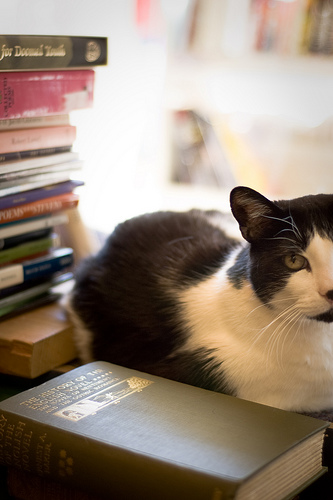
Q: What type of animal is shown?
A: Cat.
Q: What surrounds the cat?
A: Books.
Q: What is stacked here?
A: Books.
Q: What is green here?
A: The book.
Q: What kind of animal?
A: Cat.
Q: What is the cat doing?
A: Sitting.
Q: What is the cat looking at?
A: The camera.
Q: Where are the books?
A: On the table.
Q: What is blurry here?
A: The books.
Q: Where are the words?
A: On the book.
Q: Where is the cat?
A: By the books.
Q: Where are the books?
A: By the cat.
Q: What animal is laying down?
A: A cat.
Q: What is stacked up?
A: Books.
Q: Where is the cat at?
A: Next to books.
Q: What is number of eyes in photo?
A: One.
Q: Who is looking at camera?
A: The cat.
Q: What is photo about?
A: Cat and books.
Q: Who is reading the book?
A: Not the cat.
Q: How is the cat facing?
A: Forward.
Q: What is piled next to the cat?
A: Books.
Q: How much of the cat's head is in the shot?
A: Half.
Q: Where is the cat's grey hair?
A: Above eye.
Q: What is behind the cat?
A: Books on shelves.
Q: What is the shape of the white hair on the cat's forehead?
A: Pointy.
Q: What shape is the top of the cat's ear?
A: Curved.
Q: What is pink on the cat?
A: Inner ear.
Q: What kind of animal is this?
A: A cat.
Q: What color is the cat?
A: Black and white.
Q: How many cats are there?
A: One.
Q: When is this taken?
A: During the day.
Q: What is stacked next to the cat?
A: Books.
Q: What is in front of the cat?
A: A book.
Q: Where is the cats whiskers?
A: On its face.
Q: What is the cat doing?
A: Lying next to books.